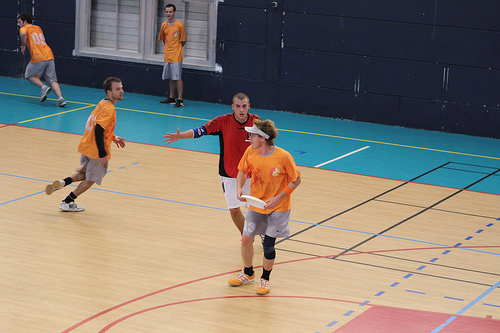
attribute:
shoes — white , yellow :
[201, 260, 311, 310]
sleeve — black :
[92, 123, 109, 158]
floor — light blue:
[352, 142, 414, 171]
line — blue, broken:
[291, 213, 498, 314]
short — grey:
[77, 141, 109, 186]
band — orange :
[278, 184, 298, 196]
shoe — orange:
[257, 278, 269, 295]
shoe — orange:
[229, 271, 253, 286]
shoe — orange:
[59, 198, 84, 210]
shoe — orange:
[46, 179, 62, 195]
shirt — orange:
[237, 141, 299, 212]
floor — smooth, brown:
[102, 239, 147, 294]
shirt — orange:
[237, 145, 297, 211]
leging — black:
[260, 230, 275, 265]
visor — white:
[239, 109, 271, 151]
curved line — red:
[98, 295, 375, 331]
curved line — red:
[61, 245, 498, 332]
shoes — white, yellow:
[230, 271, 270, 296]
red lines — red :
[58, 267, 255, 331]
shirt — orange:
[78, 98, 115, 160]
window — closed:
[83, 2, 164, 50]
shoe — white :
[58, 199, 87, 215]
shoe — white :
[42, 177, 66, 197]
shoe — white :
[256, 275, 271, 295]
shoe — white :
[226, 271, 255, 288]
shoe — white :
[38, 85, 50, 105]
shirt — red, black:
[236, 142, 307, 215]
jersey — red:
[195, 116, 253, 178]